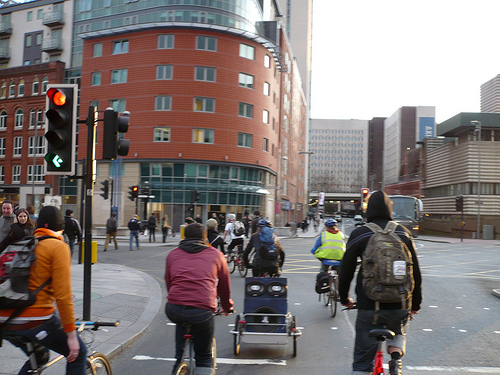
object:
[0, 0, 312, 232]
building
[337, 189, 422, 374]
man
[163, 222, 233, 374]
man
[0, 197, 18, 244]
man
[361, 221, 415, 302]
backpack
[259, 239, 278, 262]
backpack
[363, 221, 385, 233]
straps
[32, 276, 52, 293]
straps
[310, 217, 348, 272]
person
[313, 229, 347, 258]
vest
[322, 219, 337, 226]
helment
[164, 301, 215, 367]
blue jeans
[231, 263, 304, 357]
bicycle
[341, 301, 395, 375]
bicycle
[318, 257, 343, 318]
bicycle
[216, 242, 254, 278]
bicycle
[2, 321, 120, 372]
bike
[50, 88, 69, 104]
stop light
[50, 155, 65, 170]
arrow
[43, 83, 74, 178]
traffic signal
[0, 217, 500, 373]
busy road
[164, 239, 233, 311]
jacket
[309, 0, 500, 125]
clear sky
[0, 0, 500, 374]
city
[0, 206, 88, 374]
man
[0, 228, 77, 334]
jacket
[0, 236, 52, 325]
backpack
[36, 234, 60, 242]
straps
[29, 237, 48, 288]
back